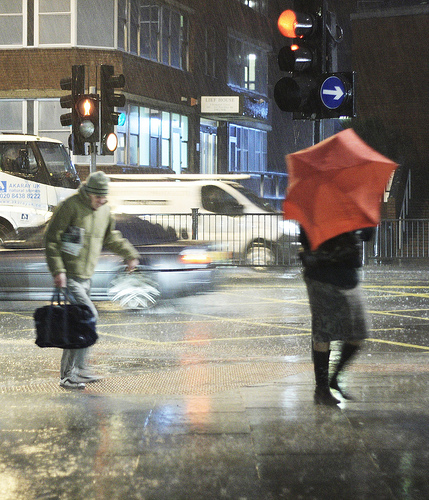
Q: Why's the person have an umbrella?
A: It's raining.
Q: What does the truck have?
A: A cab.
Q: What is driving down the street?
A: Black car.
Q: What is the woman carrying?
A: An umbrella.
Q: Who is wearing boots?
A: A woman.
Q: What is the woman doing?
A: Walking.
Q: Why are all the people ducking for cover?
A: It is pouring rain.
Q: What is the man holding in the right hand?
A: A black duffle bag.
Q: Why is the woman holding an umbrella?
A: It is raining out.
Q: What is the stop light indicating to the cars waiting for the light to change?
A: Yellow means slow down.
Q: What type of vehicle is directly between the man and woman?
A: Utility van.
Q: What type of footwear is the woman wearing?
A: Black boots.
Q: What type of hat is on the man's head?
A: Beanie cap.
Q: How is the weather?
A: Raining.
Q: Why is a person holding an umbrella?
A: It is raining.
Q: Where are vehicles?
A: In the street.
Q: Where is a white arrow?
A: On blue sign.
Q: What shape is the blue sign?
A: Round.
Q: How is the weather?
A: Rainy.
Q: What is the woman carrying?
A: An umbrella.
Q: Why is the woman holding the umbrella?
A: It's raining.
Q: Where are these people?
A: Walking on the sidewalk.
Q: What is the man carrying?
A: A duffel bag.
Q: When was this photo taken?
A: At night.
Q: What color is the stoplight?
A: Red.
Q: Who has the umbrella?
A: A lady wearing boots.